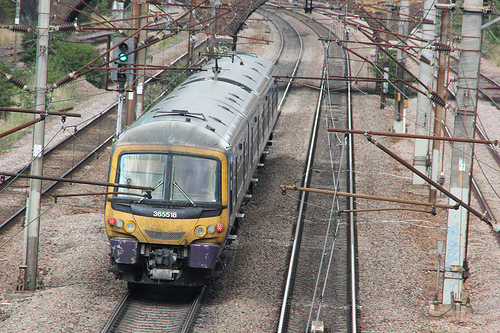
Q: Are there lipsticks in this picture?
A: No, there are no lipsticks.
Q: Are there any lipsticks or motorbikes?
A: No, there are no lipsticks or motorbikes.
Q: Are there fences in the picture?
A: No, there are no fences.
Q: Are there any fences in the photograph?
A: No, there are no fences.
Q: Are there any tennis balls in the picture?
A: No, there are no tennis balls.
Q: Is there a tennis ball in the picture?
A: No, there are no tennis balls.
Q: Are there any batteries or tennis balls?
A: No, there are no tennis balls or batteries.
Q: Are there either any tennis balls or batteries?
A: No, there are no tennis balls or batteries.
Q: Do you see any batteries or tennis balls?
A: No, there are no tennis balls or batteries.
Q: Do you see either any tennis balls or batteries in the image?
A: No, there are no tennis balls or batteries.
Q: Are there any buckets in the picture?
A: No, there are no buckets.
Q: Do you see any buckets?
A: No, there are no buckets.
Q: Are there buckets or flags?
A: No, there are no buckets or flags.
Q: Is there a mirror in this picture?
A: No, there are no mirrors.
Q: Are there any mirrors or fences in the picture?
A: No, there are no mirrors or fences.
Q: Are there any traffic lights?
A: Yes, there is a traffic light.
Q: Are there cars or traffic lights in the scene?
A: Yes, there is a traffic light.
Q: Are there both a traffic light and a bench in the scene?
A: No, there is a traffic light but no benches.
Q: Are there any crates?
A: No, there are no crates.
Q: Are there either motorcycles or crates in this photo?
A: No, there are no crates or motorcycles.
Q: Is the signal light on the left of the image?
A: Yes, the signal light is on the left of the image.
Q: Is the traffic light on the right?
A: No, the traffic light is on the left of the image.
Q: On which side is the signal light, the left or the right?
A: The signal light is on the left of the image.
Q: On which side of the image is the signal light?
A: The signal light is on the left of the image.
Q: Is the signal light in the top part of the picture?
A: Yes, the signal light is in the top of the image.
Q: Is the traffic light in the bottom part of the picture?
A: No, the traffic light is in the top of the image.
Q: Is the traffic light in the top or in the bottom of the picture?
A: The traffic light is in the top of the image.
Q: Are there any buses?
A: No, there are no buses.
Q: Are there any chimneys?
A: No, there are no chimneys.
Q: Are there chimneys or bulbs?
A: No, there are no chimneys or bulbs.